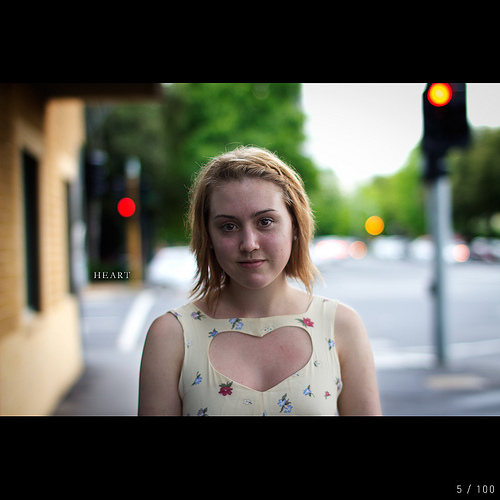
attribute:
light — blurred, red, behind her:
[115, 191, 138, 220]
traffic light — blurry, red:
[113, 178, 146, 224]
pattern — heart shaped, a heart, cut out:
[204, 328, 315, 395]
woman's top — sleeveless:
[167, 288, 345, 417]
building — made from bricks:
[2, 74, 168, 416]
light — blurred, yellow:
[425, 82, 455, 110]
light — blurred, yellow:
[362, 213, 387, 238]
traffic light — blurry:
[414, 81, 478, 189]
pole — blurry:
[420, 175, 456, 370]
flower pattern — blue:
[270, 391, 295, 416]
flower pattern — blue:
[187, 371, 206, 392]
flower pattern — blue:
[226, 315, 245, 334]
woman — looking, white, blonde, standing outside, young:
[134, 140, 387, 418]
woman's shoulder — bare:
[144, 290, 223, 359]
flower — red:
[217, 380, 236, 401]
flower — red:
[295, 314, 318, 332]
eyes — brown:
[215, 215, 277, 236]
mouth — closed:
[233, 255, 272, 272]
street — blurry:
[77, 234, 497, 423]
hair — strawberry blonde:
[186, 144, 327, 317]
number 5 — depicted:
[451, 477, 468, 498]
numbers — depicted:
[447, 477, 498, 498]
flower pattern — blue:
[295, 380, 318, 401]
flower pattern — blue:
[322, 329, 338, 352]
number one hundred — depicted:
[470, 482, 499, 494]